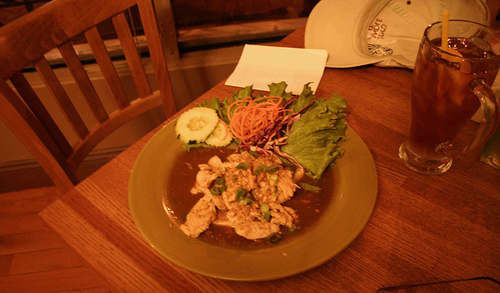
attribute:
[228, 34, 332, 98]
paper — white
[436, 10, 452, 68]
straw — yellow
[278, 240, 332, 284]
plate — green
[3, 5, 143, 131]
chair — brown, wooden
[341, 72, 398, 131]
table — wooden